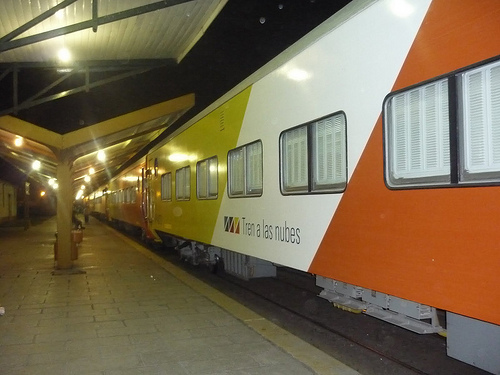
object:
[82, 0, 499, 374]
train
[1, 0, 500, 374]
train station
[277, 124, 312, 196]
window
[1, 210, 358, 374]
sidewalk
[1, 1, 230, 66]
awning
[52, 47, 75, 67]
light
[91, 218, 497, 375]
tracks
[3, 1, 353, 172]
sky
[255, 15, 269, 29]
moon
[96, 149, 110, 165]
light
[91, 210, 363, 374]
line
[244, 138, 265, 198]
window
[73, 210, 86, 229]
person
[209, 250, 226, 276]
wheel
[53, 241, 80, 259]
bench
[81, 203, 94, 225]
person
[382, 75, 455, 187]
window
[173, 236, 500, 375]
undercarriage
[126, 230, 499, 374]
concrete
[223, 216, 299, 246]
logo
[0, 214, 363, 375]
platform